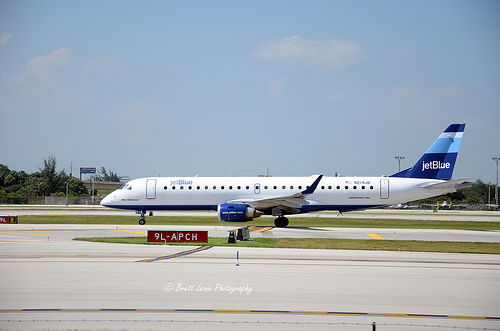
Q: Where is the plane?
A: On the runway.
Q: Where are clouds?
A: In the sky.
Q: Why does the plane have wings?
A: To be able to fly.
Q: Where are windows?
A: On side of the plane.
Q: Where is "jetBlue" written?
A: On tail of the plane.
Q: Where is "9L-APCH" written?
A: On red sign.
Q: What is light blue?
A: Sky.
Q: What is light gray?
A: Tarmac.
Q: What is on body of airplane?
A: Name of airline.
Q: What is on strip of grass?
A: Sign.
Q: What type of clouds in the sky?
A: Faint white.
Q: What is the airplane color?
A: Blue and white.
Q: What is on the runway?
A: Plane.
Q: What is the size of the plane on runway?
A: Big.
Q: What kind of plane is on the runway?
A: Huge.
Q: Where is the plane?
A: On the ground.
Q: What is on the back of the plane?
A: A blue tail.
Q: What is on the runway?
A: Airplane.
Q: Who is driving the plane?
A: Pilot.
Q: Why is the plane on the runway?
A: Taking off.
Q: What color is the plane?
A: White.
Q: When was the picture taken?
A: Daytime.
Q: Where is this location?
A: Airport.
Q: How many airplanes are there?
A: One.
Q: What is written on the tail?
A: Jetblue.